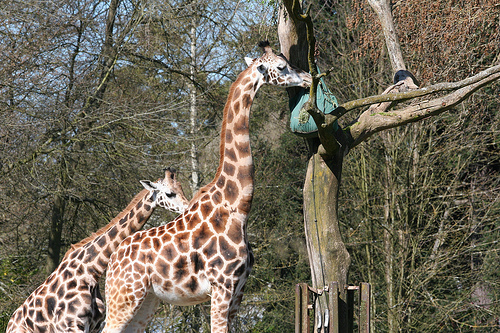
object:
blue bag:
[290, 68, 344, 137]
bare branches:
[375, 131, 499, 331]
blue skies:
[184, 1, 236, 74]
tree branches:
[18, 14, 202, 141]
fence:
[287, 280, 375, 332]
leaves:
[342, 1, 498, 85]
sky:
[0, 0, 262, 82]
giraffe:
[7, 167, 169, 333]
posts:
[291, 280, 312, 330]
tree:
[279, 3, 499, 331]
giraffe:
[83, 40, 313, 333]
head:
[240, 39, 312, 90]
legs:
[186, 269, 249, 333]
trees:
[0, 1, 500, 333]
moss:
[299, 116, 355, 330]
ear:
[136, 176, 160, 191]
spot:
[190, 219, 213, 248]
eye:
[276, 67, 286, 72]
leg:
[100, 252, 149, 333]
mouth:
[299, 78, 313, 88]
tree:
[295, 140, 365, 330]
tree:
[0, 0, 129, 219]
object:
[395, 65, 417, 86]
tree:
[190, 17, 200, 188]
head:
[136, 167, 191, 215]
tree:
[21, 17, 119, 291]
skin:
[127, 235, 221, 286]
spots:
[153, 255, 176, 283]